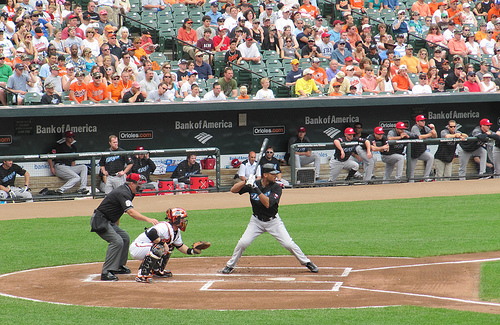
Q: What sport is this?
A: Baseball.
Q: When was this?
A: Daytime.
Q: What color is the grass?
A: Green.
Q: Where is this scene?
A: Baseball field.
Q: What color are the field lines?
A: White.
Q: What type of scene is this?
A: Outdoor.